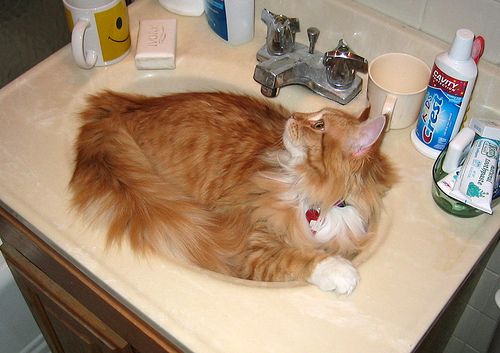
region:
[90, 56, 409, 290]
that is a cat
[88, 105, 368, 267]
that cat is brown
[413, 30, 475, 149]
that is tooth paste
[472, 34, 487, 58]
that is a tooth brush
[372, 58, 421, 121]
that is a cat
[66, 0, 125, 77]
that is a cat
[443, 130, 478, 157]
that is a bar of soap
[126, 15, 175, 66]
that is a bar of soap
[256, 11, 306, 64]
that that is a tap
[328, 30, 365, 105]
that that is a tap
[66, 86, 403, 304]
brown and white cat lying in sink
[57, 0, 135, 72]
white and yellow mug with a smiling face on counter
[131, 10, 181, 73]
wrapped bar of soap on sink counter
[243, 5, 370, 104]
silver metal faucet of bathroom sink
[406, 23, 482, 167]
tube of kid's crest with cavity protection on sink counter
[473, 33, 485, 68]
red toothbrush behind toothpaste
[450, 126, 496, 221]
toothpaste in container with other items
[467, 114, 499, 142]
floss in container with other items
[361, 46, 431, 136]
mug next to toothpaste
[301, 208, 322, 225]
red item around neck of cat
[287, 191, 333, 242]
Red ball on collar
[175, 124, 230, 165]
orange fur on cat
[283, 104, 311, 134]
orange fur on cats nose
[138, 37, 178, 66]
white bar of soap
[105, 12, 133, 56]
smiley face on cup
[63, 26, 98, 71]
white handle on cup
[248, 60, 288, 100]
silver faucet on sink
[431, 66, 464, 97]
red and white label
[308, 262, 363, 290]
front paw on cat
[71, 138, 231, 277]
long bushy tail on cat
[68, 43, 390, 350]
cat in the sink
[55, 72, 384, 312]
an orange fluffy cat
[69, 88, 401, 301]
Brown cat on the sink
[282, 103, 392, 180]
Cat's head looking upwards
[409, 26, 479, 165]
White toothpast on the sink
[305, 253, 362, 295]
Right white paws of the cat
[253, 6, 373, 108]
Silver faucet on the sink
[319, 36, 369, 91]
Right tap of the faucet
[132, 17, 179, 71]
Soap near the mug on the sink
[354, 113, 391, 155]
Left ear of the cat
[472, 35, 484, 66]
Red toothbrush behind the toothpaste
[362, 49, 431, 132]
A cup near the faucet